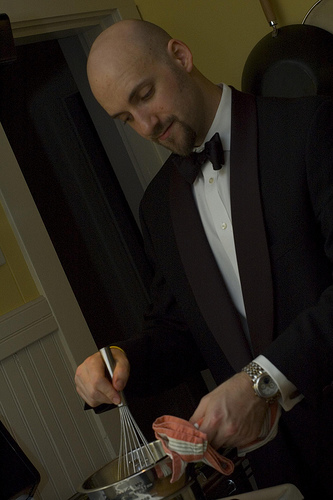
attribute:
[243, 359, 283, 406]
watch — metal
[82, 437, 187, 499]
pot — metal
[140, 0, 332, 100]
wall — yellow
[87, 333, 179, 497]
wire whisk — silver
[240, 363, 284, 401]
watch — fancy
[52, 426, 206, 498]
mixing bowl — silver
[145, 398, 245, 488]
kitchen towel — colorful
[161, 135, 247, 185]
bowtie — formal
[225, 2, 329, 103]
skillet — metal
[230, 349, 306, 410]
watch — expensive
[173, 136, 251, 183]
bowtie — black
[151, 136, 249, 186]
tie — black, bow